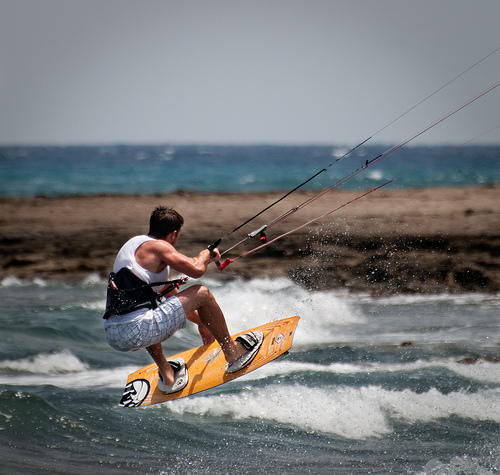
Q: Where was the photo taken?
A: It was taken at the ocean.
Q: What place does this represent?
A: It represents the ocean.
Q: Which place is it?
A: It is an ocean.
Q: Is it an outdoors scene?
A: Yes, it is outdoors.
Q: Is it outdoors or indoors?
A: It is outdoors.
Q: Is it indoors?
A: No, it is outdoors.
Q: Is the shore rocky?
A: Yes, the shore is rocky.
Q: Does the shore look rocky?
A: Yes, the shore is rocky.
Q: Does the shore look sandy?
A: No, the shore is rocky.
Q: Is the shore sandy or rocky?
A: The shore is rocky.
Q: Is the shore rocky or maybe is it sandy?
A: The shore is rocky.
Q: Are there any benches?
A: No, there are no benches.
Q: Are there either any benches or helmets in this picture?
A: No, there are no benches or helmets.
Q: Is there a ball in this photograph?
A: No, there are no balls.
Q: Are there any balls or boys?
A: No, there are no balls or boys.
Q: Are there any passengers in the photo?
A: No, there are no passengers.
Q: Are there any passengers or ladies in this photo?
A: No, there are no passengers or ladies.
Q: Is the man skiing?
A: Yes, the man is skiing.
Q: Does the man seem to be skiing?
A: Yes, the man is skiing.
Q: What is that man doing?
A: The man is skiing.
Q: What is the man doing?
A: The man is skiing.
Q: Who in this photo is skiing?
A: The man is skiing.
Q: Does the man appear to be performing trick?
A: No, the man is skiing.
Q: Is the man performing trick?
A: No, the man is skiing.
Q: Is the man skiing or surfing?
A: The man is skiing.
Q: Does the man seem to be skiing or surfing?
A: The man is skiing.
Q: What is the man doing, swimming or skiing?
A: The man is skiing.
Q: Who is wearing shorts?
A: The man is wearing shorts.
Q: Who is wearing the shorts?
A: The man is wearing shorts.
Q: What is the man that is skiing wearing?
A: The man is wearing shorts.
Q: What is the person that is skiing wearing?
A: The man is wearing shorts.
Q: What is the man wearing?
A: The man is wearing shorts.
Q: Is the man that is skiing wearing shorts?
A: Yes, the man is wearing shorts.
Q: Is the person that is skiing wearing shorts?
A: Yes, the man is wearing shorts.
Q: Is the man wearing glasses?
A: No, the man is wearing shorts.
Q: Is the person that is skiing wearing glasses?
A: No, the man is wearing shorts.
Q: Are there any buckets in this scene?
A: No, there are no buckets.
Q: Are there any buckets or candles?
A: No, there are no buckets or candles.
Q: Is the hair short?
A: Yes, the hair is short.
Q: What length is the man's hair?
A: The hair is short.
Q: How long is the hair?
A: The hair is short.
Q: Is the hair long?
A: No, the hair is short.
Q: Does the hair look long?
A: No, the hair is short.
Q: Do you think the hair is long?
A: No, the hair is short.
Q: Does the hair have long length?
A: No, the hair is short.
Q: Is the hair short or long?
A: The hair is short.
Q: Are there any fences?
A: No, there are no fences.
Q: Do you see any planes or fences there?
A: No, there are no fences or planes.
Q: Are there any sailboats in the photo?
A: No, there are no sailboats.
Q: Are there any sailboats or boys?
A: No, there are no sailboats or boys.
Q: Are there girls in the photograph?
A: No, there are no girls.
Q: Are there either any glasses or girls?
A: No, there are no girls or glasses.